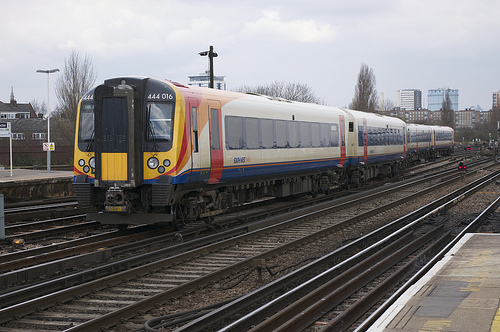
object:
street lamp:
[34, 68, 58, 172]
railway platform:
[0, 166, 75, 206]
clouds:
[384, 3, 500, 57]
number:
[147, 92, 174, 100]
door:
[207, 99, 223, 183]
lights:
[78, 159, 86, 166]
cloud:
[224, 7, 333, 53]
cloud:
[0, 0, 164, 54]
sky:
[2, 2, 499, 118]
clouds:
[317, 34, 409, 95]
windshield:
[144, 99, 174, 141]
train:
[67, 75, 454, 230]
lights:
[459, 166, 462, 170]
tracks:
[163, 171, 500, 332]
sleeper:
[134, 278, 191, 283]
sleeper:
[108, 288, 166, 293]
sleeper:
[24, 311, 101, 321]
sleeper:
[228, 247, 271, 251]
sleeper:
[200, 256, 248, 260]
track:
[2, 220, 176, 277]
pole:
[46, 73, 51, 172]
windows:
[224, 116, 244, 150]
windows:
[243, 117, 260, 150]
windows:
[260, 119, 276, 149]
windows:
[320, 123, 330, 146]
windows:
[287, 121, 300, 147]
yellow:
[73, 76, 185, 186]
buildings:
[358, 84, 500, 136]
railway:
[0, 157, 490, 332]